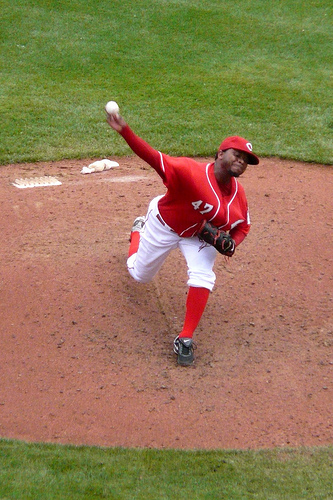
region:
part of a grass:
[181, 90, 198, 108]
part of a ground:
[181, 406, 210, 438]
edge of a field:
[160, 430, 209, 481]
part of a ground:
[226, 387, 259, 416]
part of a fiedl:
[232, 451, 256, 469]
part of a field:
[191, 452, 215, 475]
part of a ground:
[194, 428, 222, 456]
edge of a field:
[201, 428, 232, 458]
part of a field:
[221, 462, 247, 489]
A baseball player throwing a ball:
[105, 103, 258, 364]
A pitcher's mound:
[1, 152, 330, 448]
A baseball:
[103, 99, 120, 115]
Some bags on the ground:
[82, 154, 120, 175]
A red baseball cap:
[217, 132, 258, 166]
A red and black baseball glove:
[198, 220, 234, 257]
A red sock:
[126, 230, 138, 257]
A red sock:
[175, 285, 209, 338]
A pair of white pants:
[126, 196, 219, 289]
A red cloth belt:
[158, 215, 174, 233]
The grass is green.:
[1, 436, 331, 498]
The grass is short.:
[1, 436, 332, 498]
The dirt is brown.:
[0, 156, 331, 450]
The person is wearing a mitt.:
[196, 220, 235, 257]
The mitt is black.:
[196, 219, 235, 258]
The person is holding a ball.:
[100, 96, 126, 129]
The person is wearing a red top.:
[118, 123, 252, 251]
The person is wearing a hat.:
[214, 134, 259, 165]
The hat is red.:
[215, 134, 260, 166]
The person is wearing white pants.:
[124, 193, 217, 292]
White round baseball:
[104, 98, 119, 115]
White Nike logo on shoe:
[181, 335, 192, 345]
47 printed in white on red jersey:
[189, 198, 213, 219]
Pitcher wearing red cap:
[107, 101, 260, 367]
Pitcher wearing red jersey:
[105, 109, 260, 363]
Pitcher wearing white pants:
[106, 110, 259, 366]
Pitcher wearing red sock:
[101, 109, 260, 363]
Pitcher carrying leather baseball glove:
[107, 111, 260, 363]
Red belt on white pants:
[153, 211, 176, 233]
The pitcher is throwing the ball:
[68, 85, 254, 382]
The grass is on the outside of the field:
[115, 457, 191, 496]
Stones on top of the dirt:
[40, 317, 150, 395]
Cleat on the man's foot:
[160, 329, 198, 367]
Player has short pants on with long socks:
[99, 196, 237, 316]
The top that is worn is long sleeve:
[116, 112, 262, 248]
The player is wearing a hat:
[217, 125, 268, 189]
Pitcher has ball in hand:
[84, 91, 170, 175]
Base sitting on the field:
[22, 142, 75, 215]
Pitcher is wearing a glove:
[201, 220, 247, 253]